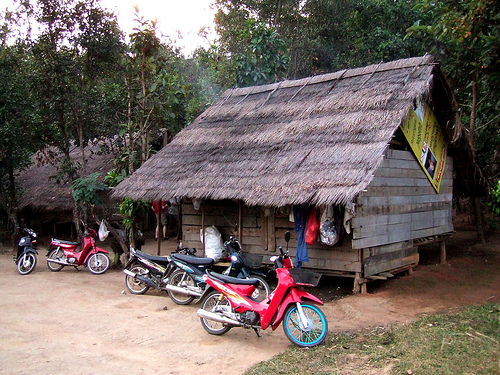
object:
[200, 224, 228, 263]
bag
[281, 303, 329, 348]
wheel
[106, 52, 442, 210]
roof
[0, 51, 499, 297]
building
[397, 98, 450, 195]
sign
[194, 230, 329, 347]
motorbike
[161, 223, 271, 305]
scooter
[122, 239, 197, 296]
scooter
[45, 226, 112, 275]
scooter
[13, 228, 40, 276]
scooter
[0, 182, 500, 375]
outside